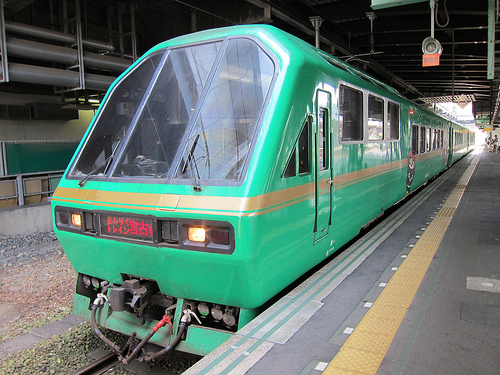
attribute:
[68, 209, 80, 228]
light — yellow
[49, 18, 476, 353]
train — green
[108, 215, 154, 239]
letters — red, Asian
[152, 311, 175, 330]
grip — red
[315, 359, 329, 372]
square — small, white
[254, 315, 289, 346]
color — blue and white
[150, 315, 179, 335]
hose — red, small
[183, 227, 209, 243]
light — small, bright, yellow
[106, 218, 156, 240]
words — oriental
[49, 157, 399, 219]
border — gold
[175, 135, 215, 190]
wiper — tall, windshield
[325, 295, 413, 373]
line — yellow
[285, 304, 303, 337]
stripe — green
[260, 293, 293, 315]
stripe — green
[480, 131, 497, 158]
people — waiting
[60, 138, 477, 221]
stripe — gold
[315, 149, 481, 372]
stripe — yellow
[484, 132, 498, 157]
person — standing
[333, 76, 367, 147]
window — small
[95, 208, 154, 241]
writing — foreign, red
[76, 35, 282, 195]
windows — three